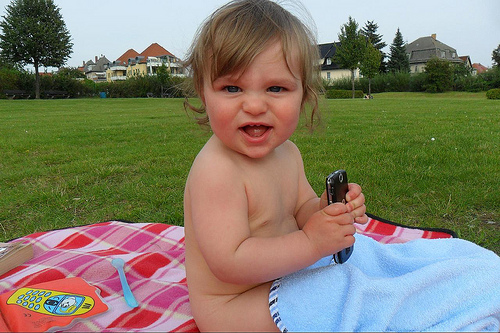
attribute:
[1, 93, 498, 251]
grass — green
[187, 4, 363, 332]
baby — sitting, happy, smiling, naked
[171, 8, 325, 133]
hair — blonde, curly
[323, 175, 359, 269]
phone — black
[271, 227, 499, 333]
towel — blue, fuzzy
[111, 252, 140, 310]
spoon — blue, plastic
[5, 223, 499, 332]
blanket — pink, red, flannel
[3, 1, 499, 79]
sky — blue, clear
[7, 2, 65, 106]
tree — tall, green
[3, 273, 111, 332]
toy — book, soft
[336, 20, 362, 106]
tree — green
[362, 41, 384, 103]
tree — green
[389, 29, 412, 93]
tree — green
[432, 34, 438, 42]
chimney — red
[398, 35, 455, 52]
roof — grey